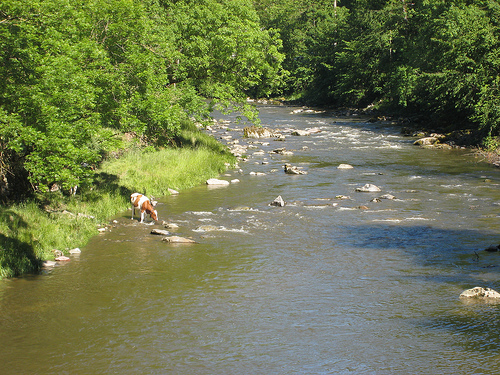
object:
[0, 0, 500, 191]
forest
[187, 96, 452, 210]
rock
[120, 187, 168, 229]
animal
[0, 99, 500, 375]
river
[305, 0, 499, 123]
bunch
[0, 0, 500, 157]
background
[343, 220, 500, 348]
shadow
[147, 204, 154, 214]
neck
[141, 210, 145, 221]
leg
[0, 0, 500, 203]
tree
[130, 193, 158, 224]
animal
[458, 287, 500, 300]
rock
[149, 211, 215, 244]
rock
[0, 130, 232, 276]
grass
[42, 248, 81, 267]
rock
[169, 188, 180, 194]
rock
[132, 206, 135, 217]
leg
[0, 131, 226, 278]
back ground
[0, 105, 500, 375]
water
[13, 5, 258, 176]
leaves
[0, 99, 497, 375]
stream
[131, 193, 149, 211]
body